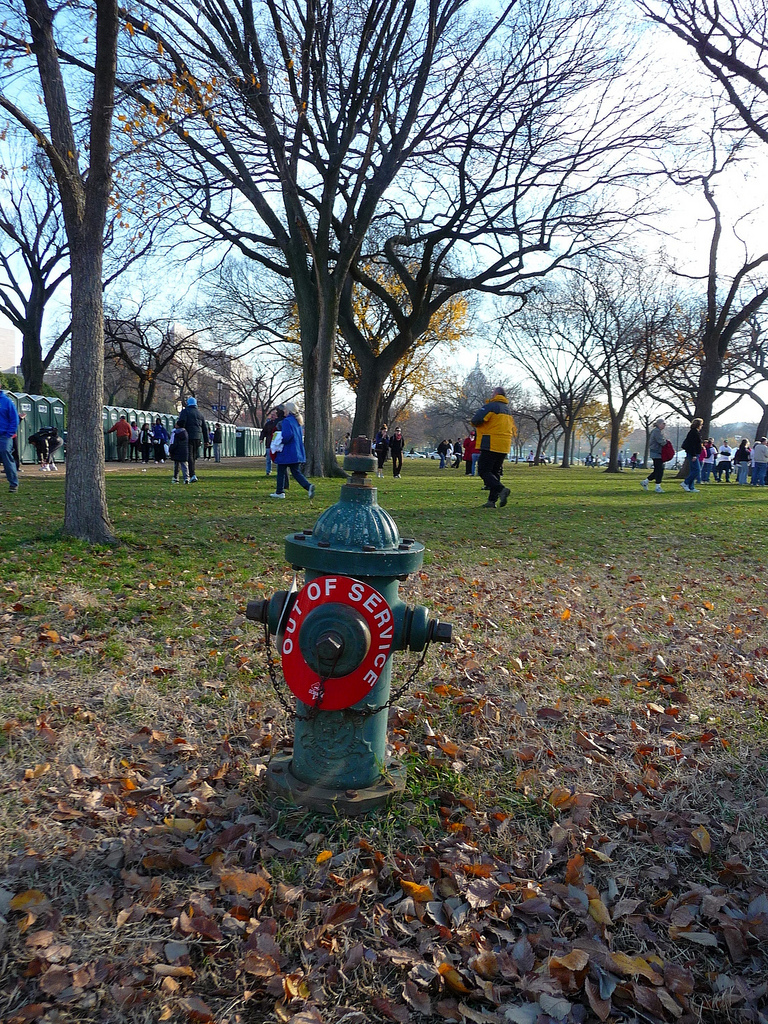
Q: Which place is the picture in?
A: It is at the park.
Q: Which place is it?
A: It is a park.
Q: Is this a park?
A: Yes, it is a park.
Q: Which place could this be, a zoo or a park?
A: It is a park.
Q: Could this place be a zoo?
A: No, it is a park.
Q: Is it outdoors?
A: Yes, it is outdoors.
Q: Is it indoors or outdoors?
A: It is outdoors.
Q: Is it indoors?
A: No, it is outdoors.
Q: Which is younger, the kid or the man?
A: The kid is younger than the man.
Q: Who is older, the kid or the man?
A: The man is older than the kid.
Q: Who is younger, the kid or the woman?
A: The kid is younger than the woman.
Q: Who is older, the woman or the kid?
A: The woman is older than the kid.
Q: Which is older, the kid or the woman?
A: The woman is older than the kid.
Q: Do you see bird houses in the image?
A: No, there are no bird houses.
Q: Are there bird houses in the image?
A: No, there are no bird houses.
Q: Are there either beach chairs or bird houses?
A: No, there are no bird houses or beach chairs.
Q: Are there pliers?
A: No, there are no pliers.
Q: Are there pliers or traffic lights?
A: No, there are no pliers or traffic lights.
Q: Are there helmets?
A: No, there are no helmets.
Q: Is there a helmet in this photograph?
A: No, there are no helmets.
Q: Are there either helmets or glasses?
A: No, there are no helmets or glasses.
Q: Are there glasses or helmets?
A: No, there are no helmets or glasses.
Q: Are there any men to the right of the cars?
A: Yes, there is a man to the right of the cars.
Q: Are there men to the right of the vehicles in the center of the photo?
A: Yes, there is a man to the right of the cars.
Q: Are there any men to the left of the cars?
A: No, the man is to the right of the cars.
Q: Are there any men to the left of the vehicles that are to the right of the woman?
A: No, the man is to the right of the cars.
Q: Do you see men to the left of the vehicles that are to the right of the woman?
A: No, the man is to the right of the cars.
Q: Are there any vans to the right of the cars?
A: No, there is a man to the right of the cars.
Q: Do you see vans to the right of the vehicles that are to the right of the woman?
A: No, there is a man to the right of the cars.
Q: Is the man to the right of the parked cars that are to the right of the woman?
A: Yes, the man is to the right of the cars.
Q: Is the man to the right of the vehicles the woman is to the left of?
A: Yes, the man is to the right of the cars.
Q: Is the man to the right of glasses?
A: No, the man is to the right of the cars.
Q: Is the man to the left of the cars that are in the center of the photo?
A: No, the man is to the right of the cars.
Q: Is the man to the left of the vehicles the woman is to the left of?
A: No, the man is to the right of the cars.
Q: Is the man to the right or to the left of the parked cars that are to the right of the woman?
A: The man is to the right of the cars.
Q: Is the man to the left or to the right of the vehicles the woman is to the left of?
A: The man is to the right of the cars.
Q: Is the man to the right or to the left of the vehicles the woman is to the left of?
A: The man is to the right of the cars.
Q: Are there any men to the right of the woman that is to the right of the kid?
A: Yes, there is a man to the right of the woman.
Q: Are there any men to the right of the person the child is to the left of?
A: Yes, there is a man to the right of the woman.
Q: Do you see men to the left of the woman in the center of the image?
A: No, the man is to the right of the woman.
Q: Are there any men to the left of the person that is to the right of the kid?
A: No, the man is to the right of the woman.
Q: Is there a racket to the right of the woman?
A: No, there is a man to the right of the woman.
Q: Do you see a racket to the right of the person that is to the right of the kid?
A: No, there is a man to the right of the woman.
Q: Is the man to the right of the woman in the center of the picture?
A: Yes, the man is to the right of the woman.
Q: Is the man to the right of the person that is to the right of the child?
A: Yes, the man is to the right of the woman.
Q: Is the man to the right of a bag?
A: No, the man is to the right of the woman.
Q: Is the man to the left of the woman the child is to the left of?
A: No, the man is to the right of the woman.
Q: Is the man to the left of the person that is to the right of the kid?
A: No, the man is to the right of the woman.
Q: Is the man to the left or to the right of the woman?
A: The man is to the right of the woman.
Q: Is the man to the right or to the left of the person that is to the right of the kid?
A: The man is to the right of the woman.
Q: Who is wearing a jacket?
A: The man is wearing a jacket.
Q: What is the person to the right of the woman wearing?
A: The man is wearing a jacket.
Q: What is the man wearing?
A: The man is wearing a jacket.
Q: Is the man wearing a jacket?
A: Yes, the man is wearing a jacket.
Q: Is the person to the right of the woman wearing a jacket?
A: Yes, the man is wearing a jacket.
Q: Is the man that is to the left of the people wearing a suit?
A: No, the man is wearing a jacket.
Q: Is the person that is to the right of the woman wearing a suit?
A: No, the man is wearing a jacket.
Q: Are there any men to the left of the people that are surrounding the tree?
A: Yes, there is a man to the left of the people.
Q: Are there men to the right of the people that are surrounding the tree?
A: No, the man is to the left of the people.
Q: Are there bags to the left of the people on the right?
A: No, there is a man to the left of the people.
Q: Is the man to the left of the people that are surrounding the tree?
A: Yes, the man is to the left of the people.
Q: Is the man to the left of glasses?
A: No, the man is to the left of the people.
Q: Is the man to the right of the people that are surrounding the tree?
A: No, the man is to the left of the people.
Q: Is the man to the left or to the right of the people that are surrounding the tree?
A: The man is to the left of the people.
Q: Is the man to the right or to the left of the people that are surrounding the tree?
A: The man is to the left of the people.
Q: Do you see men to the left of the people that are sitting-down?
A: Yes, there is a man to the left of the people.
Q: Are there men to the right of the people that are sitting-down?
A: No, the man is to the left of the people.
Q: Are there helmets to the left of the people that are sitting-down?
A: No, there is a man to the left of the people.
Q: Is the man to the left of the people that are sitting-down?
A: Yes, the man is to the left of the people.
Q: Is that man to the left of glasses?
A: No, the man is to the left of the people.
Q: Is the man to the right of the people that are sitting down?
A: No, the man is to the left of the people.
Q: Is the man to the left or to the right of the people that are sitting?
A: The man is to the left of the people.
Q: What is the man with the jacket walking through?
A: The man is walking through the grass.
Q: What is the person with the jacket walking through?
A: The man is walking through the grass.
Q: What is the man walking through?
A: The man is walking through the grass.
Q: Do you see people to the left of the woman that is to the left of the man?
A: Yes, there are people to the left of the woman.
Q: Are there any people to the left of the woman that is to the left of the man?
A: Yes, there are people to the left of the woman.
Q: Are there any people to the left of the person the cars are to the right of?
A: Yes, there are people to the left of the woman.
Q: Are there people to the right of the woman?
A: No, the people are to the left of the woman.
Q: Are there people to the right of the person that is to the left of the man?
A: No, the people are to the left of the woman.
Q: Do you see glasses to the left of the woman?
A: No, there are people to the left of the woman.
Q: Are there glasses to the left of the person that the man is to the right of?
A: No, there are people to the left of the woman.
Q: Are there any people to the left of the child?
A: Yes, there are people to the left of the child.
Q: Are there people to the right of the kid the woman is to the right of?
A: No, the people are to the left of the kid.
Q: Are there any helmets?
A: No, there are no helmets.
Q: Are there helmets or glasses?
A: No, there are no helmets or glasses.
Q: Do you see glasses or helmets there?
A: No, there are no helmets or glasses.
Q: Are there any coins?
A: No, there are no coins.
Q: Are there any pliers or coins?
A: No, there are no coins or pliers.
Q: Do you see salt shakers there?
A: No, there are no salt shakers.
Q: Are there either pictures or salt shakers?
A: No, there are no salt shakers or pictures.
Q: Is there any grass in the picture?
A: Yes, there is grass.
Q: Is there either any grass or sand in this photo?
A: Yes, there is grass.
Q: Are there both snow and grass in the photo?
A: No, there is grass but no snow.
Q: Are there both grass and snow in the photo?
A: No, there is grass but no snow.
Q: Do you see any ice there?
A: No, there is no ice.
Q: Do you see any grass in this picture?
A: Yes, there is grass.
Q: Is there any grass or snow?
A: Yes, there is grass.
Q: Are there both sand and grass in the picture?
A: No, there is grass but no sand.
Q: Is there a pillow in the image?
A: No, there are no pillows.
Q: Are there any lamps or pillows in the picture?
A: No, there are no pillows or lamps.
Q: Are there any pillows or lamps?
A: No, there are no pillows or lamps.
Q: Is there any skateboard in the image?
A: No, there are no skateboards.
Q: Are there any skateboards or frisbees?
A: No, there are no skateboards or frisbees.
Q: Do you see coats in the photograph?
A: Yes, there is a coat.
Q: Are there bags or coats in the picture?
A: Yes, there is a coat.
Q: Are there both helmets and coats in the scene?
A: No, there is a coat but no helmets.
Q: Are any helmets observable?
A: No, there are no helmets.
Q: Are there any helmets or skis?
A: No, there are no helmets or skis.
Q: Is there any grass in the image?
A: Yes, there is grass.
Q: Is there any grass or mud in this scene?
A: Yes, there is grass.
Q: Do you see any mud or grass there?
A: Yes, there is grass.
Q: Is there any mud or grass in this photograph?
A: Yes, there is grass.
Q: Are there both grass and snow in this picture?
A: No, there is grass but no snow.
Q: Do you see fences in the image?
A: No, there are no fences.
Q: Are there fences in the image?
A: No, there are no fences.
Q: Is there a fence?
A: No, there are no fences.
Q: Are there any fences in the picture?
A: No, there are no fences.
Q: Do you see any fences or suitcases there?
A: No, there are no fences or suitcases.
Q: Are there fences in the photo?
A: No, there are no fences.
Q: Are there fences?
A: No, there are no fences.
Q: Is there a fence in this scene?
A: No, there are no fences.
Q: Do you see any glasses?
A: No, there are no glasses.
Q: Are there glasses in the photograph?
A: No, there are no glasses.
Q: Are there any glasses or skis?
A: No, there are no glasses or skis.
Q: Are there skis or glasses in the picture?
A: No, there are no glasses or skis.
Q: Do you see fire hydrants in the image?
A: Yes, there is a fire hydrant.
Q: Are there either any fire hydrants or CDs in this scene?
A: Yes, there is a fire hydrant.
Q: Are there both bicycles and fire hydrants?
A: No, there is a fire hydrant but no bicycles.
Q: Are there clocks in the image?
A: No, there are no clocks.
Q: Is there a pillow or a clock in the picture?
A: No, there are no clocks or pillows.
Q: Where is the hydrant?
A: The hydrant is in the grass.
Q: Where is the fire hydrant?
A: The hydrant is in the grass.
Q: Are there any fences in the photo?
A: No, there are no fences.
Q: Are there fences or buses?
A: No, there are no fences or buses.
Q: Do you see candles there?
A: No, there are no candles.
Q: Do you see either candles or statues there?
A: No, there are no candles or statues.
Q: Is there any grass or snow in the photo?
A: Yes, there is grass.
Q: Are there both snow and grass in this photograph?
A: No, there is grass but no snow.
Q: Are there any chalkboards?
A: No, there are no chalkboards.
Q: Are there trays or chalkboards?
A: No, there are no chalkboards or trays.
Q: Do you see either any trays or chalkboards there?
A: No, there are no chalkboards or trays.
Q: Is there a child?
A: Yes, there is a child.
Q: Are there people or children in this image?
A: Yes, there is a child.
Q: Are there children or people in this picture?
A: Yes, there is a child.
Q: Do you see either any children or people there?
A: Yes, there is a child.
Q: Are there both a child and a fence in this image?
A: No, there is a child but no fences.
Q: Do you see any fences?
A: No, there are no fences.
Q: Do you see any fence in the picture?
A: No, there are no fences.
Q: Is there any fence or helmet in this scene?
A: No, there are no fences or helmets.